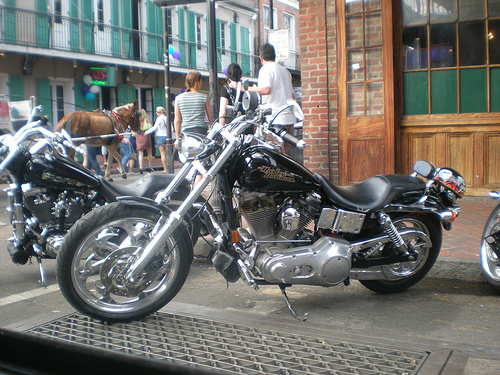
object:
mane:
[106, 102, 141, 114]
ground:
[418, 220, 493, 350]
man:
[226, 42, 296, 155]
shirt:
[254, 61, 299, 126]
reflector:
[229, 226, 238, 244]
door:
[1, 2, 18, 43]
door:
[228, 23, 236, 71]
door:
[35, 3, 50, 49]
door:
[67, 0, 95, 52]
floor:
[51, 42, 168, 68]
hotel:
[37, 1, 219, 124]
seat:
[315, 173, 427, 207]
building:
[295, 3, 496, 199]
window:
[458, 67, 488, 113]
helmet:
[426, 165, 466, 197]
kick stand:
[277, 283, 305, 320]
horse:
[50, 69, 166, 177]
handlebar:
[274, 126, 305, 151]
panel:
[406, 127, 438, 173]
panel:
[441, 127, 474, 188]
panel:
[482, 127, 499, 190]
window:
[486, 65, 499, 114]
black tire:
[55, 201, 194, 321]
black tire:
[352, 210, 443, 294]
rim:
[371, 216, 432, 279]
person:
[145, 104, 170, 172]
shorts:
[155, 138, 166, 148]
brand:
[257, 163, 301, 182]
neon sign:
[87, 65, 113, 84]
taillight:
[437, 206, 457, 221]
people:
[174, 72, 209, 190]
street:
[1, 166, 498, 374]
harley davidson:
[55, 80, 467, 320]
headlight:
[176, 131, 201, 157]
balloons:
[82, 92, 93, 100]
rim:
[70, 219, 178, 313]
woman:
[220, 64, 243, 159]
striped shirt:
[169, 90, 211, 135]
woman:
[135, 110, 150, 175]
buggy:
[0, 101, 147, 153]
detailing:
[212, 249, 239, 283]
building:
[4, 1, 258, 161]